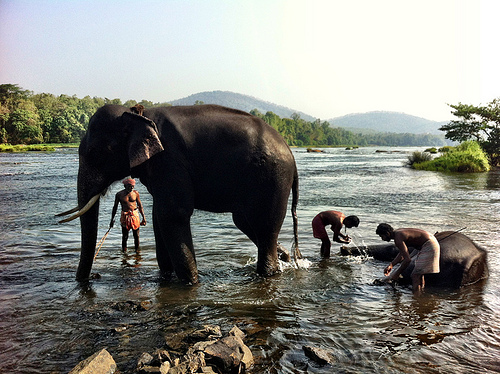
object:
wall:
[426, 159, 472, 174]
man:
[109, 178, 147, 253]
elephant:
[53, 103, 302, 284]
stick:
[93, 220, 116, 264]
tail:
[291, 162, 300, 260]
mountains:
[171, 90, 453, 149]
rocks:
[82, 324, 258, 372]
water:
[0, 142, 498, 370]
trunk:
[53, 193, 99, 224]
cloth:
[413, 239, 441, 274]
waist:
[412, 227, 423, 247]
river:
[1, 146, 499, 371]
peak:
[159, 90, 294, 116]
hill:
[167, 88, 322, 128]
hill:
[326, 107, 447, 134]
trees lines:
[0, 84, 455, 149]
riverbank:
[1, 145, 78, 154]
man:
[311, 210, 360, 258]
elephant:
[338, 230, 489, 288]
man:
[375, 222, 440, 295]